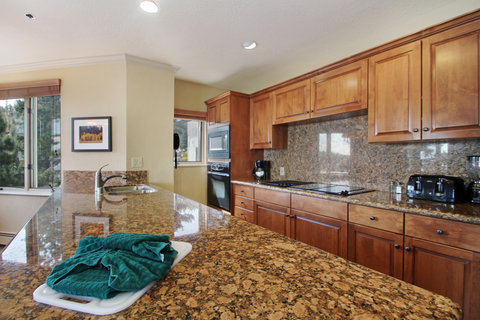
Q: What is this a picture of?
A: Kitchen.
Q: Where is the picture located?
A: Wall.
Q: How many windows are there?
A: Two.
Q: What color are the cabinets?
A: Brown.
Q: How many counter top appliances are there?
A: Three.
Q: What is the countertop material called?
A: Marble.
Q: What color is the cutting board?
A: White.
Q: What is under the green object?
A: Cutting Board.